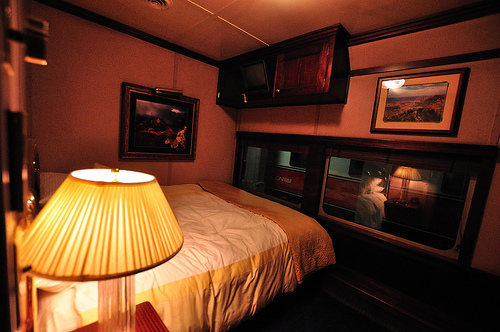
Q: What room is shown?
A: Bedroom.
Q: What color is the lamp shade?
A: Light yellow.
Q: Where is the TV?
A: On the wall.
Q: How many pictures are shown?
A: Two.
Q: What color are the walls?
A: Tan.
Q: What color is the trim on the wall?
A: Brown.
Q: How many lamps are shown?
A: One.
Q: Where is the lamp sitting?
A: Table.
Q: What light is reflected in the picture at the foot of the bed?
A: Light on the wall.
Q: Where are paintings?
A: On the wall.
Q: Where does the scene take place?
A: In a bedroom.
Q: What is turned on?
A: Lamp.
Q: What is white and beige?
A: Bedspread.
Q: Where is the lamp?
A: On side table.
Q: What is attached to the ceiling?
A: Cabinets.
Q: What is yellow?
A: Lamp shade.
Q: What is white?
A: Walls.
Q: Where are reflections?
A: On picture frame.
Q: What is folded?
A: A blanket.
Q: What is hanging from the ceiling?
A: Wooden cabinets.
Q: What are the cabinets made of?
A: Wood.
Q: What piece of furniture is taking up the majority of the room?
A: Bed.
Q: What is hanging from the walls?
A: Painting.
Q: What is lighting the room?
A: Lamp.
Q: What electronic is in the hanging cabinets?
A: Television.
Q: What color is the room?
A: Purple.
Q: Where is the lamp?
A: Next to the bed.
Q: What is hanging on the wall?
A: Painting.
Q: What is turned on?
A: The lamp.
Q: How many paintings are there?
A: Two.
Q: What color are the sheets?
A: White and yellow.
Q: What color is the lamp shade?
A: Yellow.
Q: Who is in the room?
A: No one.